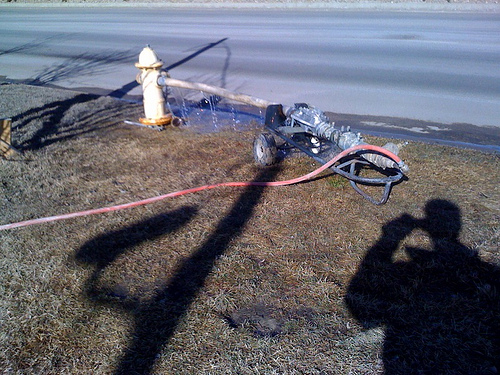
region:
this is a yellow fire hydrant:
[135, 42, 198, 141]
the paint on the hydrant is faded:
[119, 29, 209, 144]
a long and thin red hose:
[5, 128, 408, 235]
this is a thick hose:
[152, 68, 279, 125]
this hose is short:
[151, 65, 278, 112]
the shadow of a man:
[317, 189, 498, 346]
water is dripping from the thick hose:
[155, 73, 260, 134]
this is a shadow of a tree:
[28, 37, 125, 89]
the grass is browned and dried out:
[55, 218, 245, 348]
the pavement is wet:
[206, 77, 498, 157]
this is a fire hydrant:
[123, 43, 192, 140]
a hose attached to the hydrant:
[156, 55, 283, 125]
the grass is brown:
[126, 214, 320, 325]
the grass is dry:
[150, 249, 327, 356]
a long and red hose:
[2, 125, 392, 237]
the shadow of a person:
[345, 171, 497, 338]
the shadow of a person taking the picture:
[333, 173, 497, 359]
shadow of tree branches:
[30, 37, 121, 92]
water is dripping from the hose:
[161, 74, 257, 131]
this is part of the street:
[265, 20, 470, 82]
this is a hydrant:
[130, 38, 172, 130]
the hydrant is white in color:
[141, 83, 160, 106]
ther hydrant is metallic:
[134, 55, 161, 107]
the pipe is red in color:
[156, 186, 198, 203]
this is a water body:
[342, 41, 497, 96]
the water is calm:
[343, 27, 483, 92]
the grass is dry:
[213, 275, 288, 318]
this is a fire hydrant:
[122, 32, 190, 149]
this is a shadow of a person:
[347, 175, 497, 373]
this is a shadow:
[75, 197, 152, 274]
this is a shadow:
[121, 279, 172, 365]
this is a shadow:
[172, 231, 234, 294]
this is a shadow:
[221, 172, 263, 242]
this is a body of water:
[349, 32, 429, 110]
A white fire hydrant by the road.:
[125, 38, 184, 130]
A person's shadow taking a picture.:
[336, 179, 498, 374]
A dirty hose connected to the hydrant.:
[152, 67, 188, 98]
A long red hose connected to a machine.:
[3, 144, 410, 251]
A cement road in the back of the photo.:
[0, 2, 498, 156]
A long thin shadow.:
[64, 139, 289, 371]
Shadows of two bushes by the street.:
[1, 27, 141, 100]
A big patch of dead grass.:
[3, 82, 499, 372]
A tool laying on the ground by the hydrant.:
[116, 116, 171, 134]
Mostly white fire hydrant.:
[133, 44, 175, 125]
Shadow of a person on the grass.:
[344, 197, 499, 374]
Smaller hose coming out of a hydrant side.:
[157, 74, 292, 115]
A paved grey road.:
[1, 4, 498, 128]